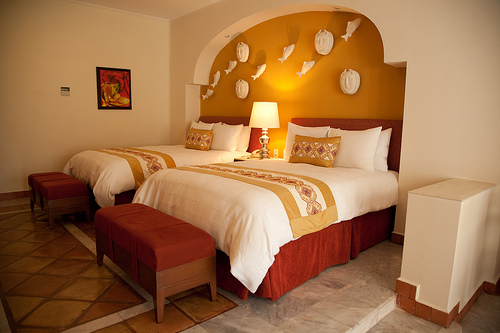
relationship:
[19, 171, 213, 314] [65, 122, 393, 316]
bench in front of bed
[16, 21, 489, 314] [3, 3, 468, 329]
indoor scene of a bedroom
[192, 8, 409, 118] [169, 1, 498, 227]
decoration on wall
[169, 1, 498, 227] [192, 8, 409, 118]
wall with decoration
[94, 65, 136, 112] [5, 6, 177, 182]
painting on wall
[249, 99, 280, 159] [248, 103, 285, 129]
lamp with shade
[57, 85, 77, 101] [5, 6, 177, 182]
thermostat on wall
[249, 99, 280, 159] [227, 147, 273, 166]
lamp on table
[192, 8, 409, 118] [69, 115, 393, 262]
ornaments above bed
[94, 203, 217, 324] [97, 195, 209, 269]
ottoman has cloth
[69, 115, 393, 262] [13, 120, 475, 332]
bed on right of room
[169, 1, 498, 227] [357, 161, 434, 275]
wall next to bed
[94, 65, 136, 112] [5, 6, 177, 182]
picture on wall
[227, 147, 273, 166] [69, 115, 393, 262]
table between bed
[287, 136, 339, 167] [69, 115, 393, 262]
pillow on bed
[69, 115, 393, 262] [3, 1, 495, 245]
beds in room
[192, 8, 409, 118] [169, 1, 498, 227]
fix on wall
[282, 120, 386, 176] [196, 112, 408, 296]
pillows on bed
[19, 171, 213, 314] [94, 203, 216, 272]
bench with cloth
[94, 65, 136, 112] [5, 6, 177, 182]
artwork on wall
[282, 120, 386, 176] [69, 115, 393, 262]
pillow on bed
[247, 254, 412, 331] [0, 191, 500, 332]
tiles on tiles